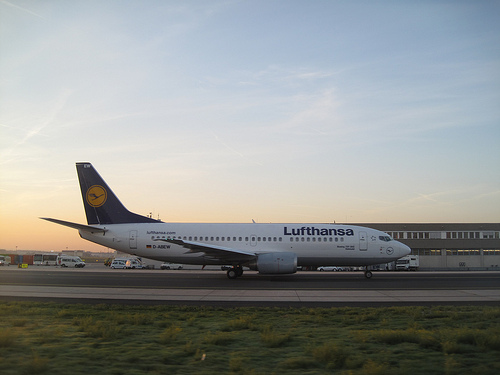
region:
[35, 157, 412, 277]
a Lufthansa plane on the runway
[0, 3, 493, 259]
a sky behind the airport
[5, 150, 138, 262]
a sunset behind the airport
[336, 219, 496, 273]
a building behind the plane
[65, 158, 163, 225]
the tail is blue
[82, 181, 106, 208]
the symbol is orange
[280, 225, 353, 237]
the letters are blue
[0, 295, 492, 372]
grass in front of the runway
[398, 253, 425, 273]
a truck in front of the building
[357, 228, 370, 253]
a door in the airplane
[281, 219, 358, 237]
The writing on the plane is blue.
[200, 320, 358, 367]
The grass in the forefront is green.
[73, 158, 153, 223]
The plane tail is blue and yellow.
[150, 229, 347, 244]
The plane has many windows.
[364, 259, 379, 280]
The front plane wheel is black.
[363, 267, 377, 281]
The front plane wheel is round.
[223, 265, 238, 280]
The back wheel is black.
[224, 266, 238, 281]
The back wheel is round.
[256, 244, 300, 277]
The jet engine cover is grey.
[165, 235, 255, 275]
The wing of the plane is silver.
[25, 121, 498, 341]
this is a plane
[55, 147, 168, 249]
blue tail on plane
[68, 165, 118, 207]
yellow decal on plane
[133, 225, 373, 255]
a row of windows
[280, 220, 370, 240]
blue writing on plane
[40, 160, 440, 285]
the plane is white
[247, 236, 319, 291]
engine of the plane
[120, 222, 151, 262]
door of the plane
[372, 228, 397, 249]
front window on plante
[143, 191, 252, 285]
wing of the plane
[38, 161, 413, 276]
a white jet airplane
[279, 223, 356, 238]
painted Lufthansa corporate logo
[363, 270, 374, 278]
airplane front landing gear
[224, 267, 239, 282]
airplane rear landing gear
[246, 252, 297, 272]
a white jet engine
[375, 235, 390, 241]
an airplane cockpit window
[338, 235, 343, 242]
an airplane passenger window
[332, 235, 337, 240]
an airplane passenger window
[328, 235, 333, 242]
an airplane passenger window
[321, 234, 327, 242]
an airplane passenger window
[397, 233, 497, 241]
Row of windows on the building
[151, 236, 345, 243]
Row of windows on the plane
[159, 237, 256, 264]
Blue and white wing of the plane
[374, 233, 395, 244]
Windshield of plane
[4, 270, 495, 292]
The airport runway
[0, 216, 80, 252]
The pink sunset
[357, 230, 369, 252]
The airplane door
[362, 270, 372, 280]
The airplane's front wheels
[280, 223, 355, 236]
The company logo on the plane is Lufthansa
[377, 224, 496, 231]
The brown roof of the building